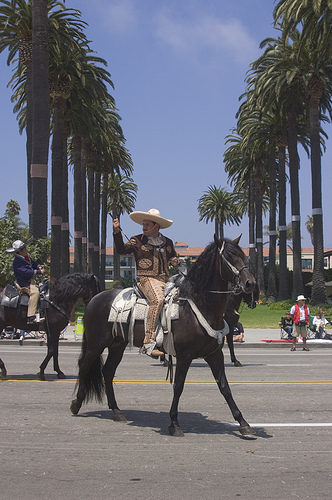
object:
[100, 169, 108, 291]
tree trunk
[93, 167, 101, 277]
tree trunk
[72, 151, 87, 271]
tree trunk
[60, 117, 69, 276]
tree trunk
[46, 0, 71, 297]
tree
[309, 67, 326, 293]
trunk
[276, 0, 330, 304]
tree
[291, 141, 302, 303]
trunk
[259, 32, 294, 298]
tree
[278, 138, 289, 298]
straight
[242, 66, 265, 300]
tree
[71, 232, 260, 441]
horse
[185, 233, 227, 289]
mane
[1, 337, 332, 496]
road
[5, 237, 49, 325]
man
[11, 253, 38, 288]
jacket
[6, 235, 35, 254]
hat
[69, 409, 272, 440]
shadow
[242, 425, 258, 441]
hoof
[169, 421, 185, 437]
hoof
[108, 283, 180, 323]
saddle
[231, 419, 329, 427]
line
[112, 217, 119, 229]
hand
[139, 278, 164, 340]
leg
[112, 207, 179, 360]
man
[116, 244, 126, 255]
elbow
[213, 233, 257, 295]
head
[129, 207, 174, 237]
head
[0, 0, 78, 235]
palm trees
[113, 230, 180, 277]
top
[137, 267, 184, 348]
pants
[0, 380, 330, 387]
line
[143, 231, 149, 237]
chin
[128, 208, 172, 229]
hat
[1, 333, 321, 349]
curb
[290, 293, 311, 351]
man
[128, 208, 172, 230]
sombero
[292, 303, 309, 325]
vest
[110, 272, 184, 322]
blanket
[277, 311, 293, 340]
boy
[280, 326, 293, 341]
chair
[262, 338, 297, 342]
towel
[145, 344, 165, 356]
foot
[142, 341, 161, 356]
stirrup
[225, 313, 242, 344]
person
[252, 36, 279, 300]
tree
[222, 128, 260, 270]
tree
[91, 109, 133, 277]
tree